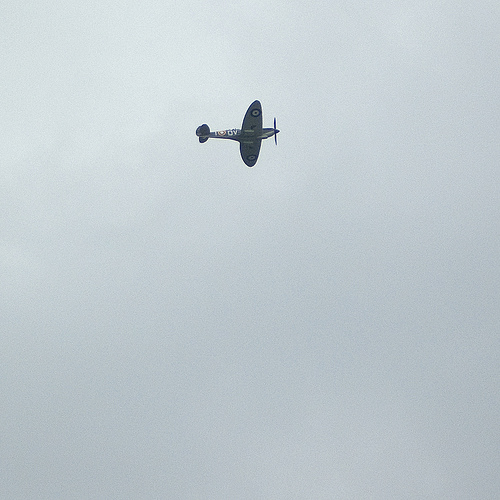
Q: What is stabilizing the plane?
A: Wings.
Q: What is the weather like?
A: Overcast.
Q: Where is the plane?
A: The sky.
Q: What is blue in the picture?
A: The sky.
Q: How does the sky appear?
A: Cloudless.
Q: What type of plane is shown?
A: A military plane.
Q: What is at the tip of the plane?
A: A propeller.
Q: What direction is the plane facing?
A: Right.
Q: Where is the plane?
A: In the sky.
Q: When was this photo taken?
A: During the day.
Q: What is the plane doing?
A: Flying.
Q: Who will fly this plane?
A: A pilot.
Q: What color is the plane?
A: Silver.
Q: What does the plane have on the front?
A: A propeller.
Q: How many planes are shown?
A: One.